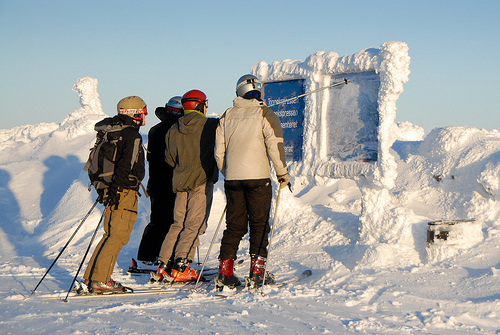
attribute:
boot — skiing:
[85, 273, 137, 296]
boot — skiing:
[211, 253, 245, 293]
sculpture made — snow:
[311, 34, 439, 232]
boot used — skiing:
[320, 183, 404, 271]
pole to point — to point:
[263, 71, 371, 112]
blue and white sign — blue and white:
[256, 67, 394, 183]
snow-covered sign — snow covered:
[246, 44, 424, 203]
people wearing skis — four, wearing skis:
[54, 51, 376, 329]